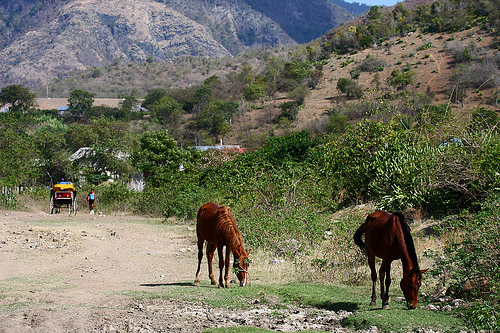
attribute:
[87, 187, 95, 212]
woman — walking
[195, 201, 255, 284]
horse — light brown, grazing, brown, eating, smaller, lighter brown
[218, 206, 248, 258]
mane — brown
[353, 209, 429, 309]
horse — brown, grazing, eating, darker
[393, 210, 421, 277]
mane — black, dark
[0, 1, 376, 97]
mountains — tall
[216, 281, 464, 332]
grass — green, for horses, short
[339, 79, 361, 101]
shrub — green, leafy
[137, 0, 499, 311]
hill — sparse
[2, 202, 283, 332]
dirt road — for riding horses, wide, winding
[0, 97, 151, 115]
building — distant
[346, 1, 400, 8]
sky — blue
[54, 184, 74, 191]
load — yellow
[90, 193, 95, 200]
shirt — blue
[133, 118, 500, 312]
vegetation — green